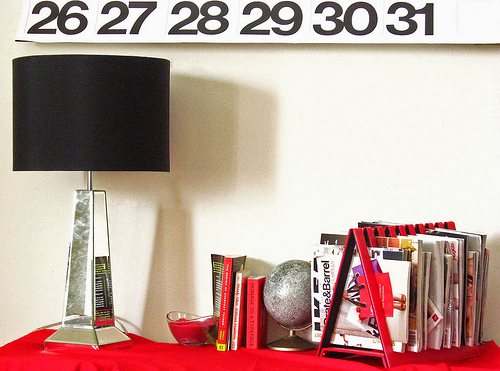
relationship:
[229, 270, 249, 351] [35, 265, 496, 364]
book on table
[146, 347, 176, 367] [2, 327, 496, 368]
cloth over table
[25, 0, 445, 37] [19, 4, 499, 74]
numbers top of photo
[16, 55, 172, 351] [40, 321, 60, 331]
lamp part of cord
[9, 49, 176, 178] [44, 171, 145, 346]
blackshade on lamp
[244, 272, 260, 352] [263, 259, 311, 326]
book between sphere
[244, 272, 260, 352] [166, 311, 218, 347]
book between candle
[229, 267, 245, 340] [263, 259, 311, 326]
book between sphere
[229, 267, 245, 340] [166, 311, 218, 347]
book between candle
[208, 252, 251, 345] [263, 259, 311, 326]
book between sphere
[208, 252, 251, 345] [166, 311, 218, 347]
book between candle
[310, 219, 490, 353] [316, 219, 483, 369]
magazine on rack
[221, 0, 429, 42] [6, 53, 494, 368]
numbers above items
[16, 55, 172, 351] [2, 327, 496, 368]
lamp on table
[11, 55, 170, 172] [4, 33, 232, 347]
blackshade on lamp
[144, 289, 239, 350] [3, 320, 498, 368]
candle on table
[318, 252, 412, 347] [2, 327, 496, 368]
magazine on table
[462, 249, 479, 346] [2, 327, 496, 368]
magazine on table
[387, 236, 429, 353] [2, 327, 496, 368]
magazine on table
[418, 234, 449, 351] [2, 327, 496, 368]
magazine on table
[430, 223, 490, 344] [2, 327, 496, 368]
magazine on table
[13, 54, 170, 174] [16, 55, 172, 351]
lampshade on lamp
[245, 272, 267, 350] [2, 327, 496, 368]
book on table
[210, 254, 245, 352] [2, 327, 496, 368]
book on table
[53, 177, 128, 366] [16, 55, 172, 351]
base of lamp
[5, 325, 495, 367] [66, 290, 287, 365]
red cloth on surface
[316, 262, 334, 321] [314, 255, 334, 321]
writing on magazine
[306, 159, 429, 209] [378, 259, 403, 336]
wall behind magazine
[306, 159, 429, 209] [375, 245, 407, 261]
wall behind magazine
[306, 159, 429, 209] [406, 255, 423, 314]
wall behind magazine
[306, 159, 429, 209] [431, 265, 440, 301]
wall behind magazine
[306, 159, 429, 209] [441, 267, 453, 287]
wall behind magazine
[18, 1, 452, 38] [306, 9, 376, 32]
background of number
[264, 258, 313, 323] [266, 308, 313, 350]
sphere on holder